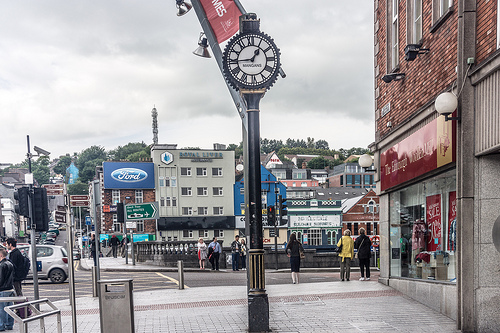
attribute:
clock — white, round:
[223, 34, 288, 93]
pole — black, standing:
[216, 18, 300, 332]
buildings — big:
[77, 131, 378, 259]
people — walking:
[193, 228, 383, 282]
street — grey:
[25, 260, 399, 307]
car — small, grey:
[9, 239, 72, 285]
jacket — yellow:
[330, 233, 358, 261]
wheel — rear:
[45, 264, 70, 286]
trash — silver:
[90, 275, 140, 331]